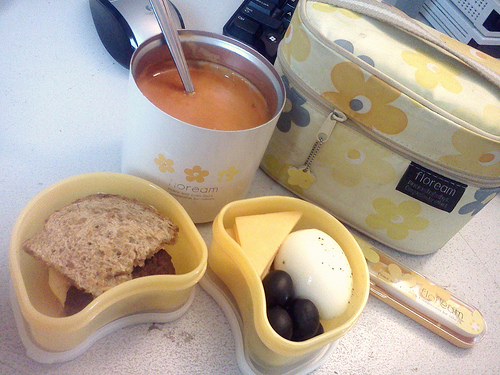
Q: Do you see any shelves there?
A: No, there are no shelves.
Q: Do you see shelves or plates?
A: No, there are no shelves or plates.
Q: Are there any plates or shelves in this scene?
A: No, there are no shelves or plates.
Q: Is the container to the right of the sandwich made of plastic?
A: Yes, the container is made of plastic.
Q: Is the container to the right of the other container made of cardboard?
A: No, the container is made of plastic.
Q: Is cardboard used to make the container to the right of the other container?
A: No, the container is made of plastic.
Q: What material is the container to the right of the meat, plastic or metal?
A: The container is made of plastic.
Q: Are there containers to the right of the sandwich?
A: Yes, there is a container to the right of the sandwich.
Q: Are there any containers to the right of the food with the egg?
A: Yes, there is a container to the right of the sandwich.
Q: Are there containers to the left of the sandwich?
A: No, the container is to the right of the sandwich.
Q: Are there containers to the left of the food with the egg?
A: No, the container is to the right of the sandwich.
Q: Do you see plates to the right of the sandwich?
A: No, there is a container to the right of the sandwich.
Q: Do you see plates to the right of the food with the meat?
A: No, there is a container to the right of the sandwich.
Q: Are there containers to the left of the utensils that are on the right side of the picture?
A: Yes, there is a container to the left of the utensils.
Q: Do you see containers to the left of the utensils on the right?
A: Yes, there is a container to the left of the utensils.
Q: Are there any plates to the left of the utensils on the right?
A: No, there is a container to the left of the utensils.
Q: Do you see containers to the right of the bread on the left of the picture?
A: Yes, there is a container to the right of the bread.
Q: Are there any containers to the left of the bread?
A: No, the container is to the right of the bread.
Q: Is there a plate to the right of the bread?
A: No, there is a container to the right of the bread.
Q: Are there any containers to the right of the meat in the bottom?
A: Yes, there is a container to the right of the meat.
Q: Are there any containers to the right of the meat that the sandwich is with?
A: Yes, there is a container to the right of the meat.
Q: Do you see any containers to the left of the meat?
A: No, the container is to the right of the meat.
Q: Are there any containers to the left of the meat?
A: No, the container is to the right of the meat.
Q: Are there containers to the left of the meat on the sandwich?
A: No, the container is to the right of the meat.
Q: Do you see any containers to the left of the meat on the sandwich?
A: No, the container is to the right of the meat.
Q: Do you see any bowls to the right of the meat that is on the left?
A: No, there is a container to the right of the meat.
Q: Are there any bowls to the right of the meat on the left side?
A: No, there is a container to the right of the meat.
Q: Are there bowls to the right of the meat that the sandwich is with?
A: No, there is a container to the right of the meat.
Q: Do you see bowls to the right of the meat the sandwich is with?
A: No, there is a container to the right of the meat.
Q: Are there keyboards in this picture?
A: Yes, there is a keyboard.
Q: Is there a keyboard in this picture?
A: Yes, there is a keyboard.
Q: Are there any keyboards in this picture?
A: Yes, there is a keyboard.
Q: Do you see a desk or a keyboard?
A: Yes, there is a keyboard.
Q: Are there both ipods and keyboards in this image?
A: No, there is a keyboard but no ipods.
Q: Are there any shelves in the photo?
A: No, there are no shelves.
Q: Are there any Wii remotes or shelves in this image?
A: No, there are no shelves or Wii remotes.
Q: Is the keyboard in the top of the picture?
A: Yes, the keyboard is in the top of the image.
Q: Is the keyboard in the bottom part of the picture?
A: No, the keyboard is in the top of the image.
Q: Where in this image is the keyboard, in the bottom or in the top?
A: The keyboard is in the top of the image.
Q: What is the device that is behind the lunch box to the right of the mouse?
A: The device is a keyboard.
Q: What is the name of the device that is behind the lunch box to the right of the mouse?
A: The device is a keyboard.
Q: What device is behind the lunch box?
A: The device is a keyboard.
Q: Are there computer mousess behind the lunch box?
A: No, there is a keyboard behind the lunch box.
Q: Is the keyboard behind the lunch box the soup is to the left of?
A: Yes, the keyboard is behind the lunch box.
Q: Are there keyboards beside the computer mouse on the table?
A: Yes, there is a keyboard beside the mouse.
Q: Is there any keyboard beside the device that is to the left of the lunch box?
A: Yes, there is a keyboard beside the mouse.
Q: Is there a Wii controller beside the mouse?
A: No, there is a keyboard beside the mouse.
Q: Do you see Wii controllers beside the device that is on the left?
A: No, there is a keyboard beside the mouse.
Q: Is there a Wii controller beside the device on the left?
A: No, there is a keyboard beside the mouse.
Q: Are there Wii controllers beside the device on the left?
A: No, there is a keyboard beside the mouse.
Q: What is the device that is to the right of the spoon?
A: The device is a keyboard.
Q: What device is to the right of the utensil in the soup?
A: The device is a keyboard.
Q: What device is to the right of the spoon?
A: The device is a keyboard.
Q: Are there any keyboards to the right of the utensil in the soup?
A: Yes, there is a keyboard to the right of the spoon.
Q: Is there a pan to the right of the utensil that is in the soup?
A: No, there is a keyboard to the right of the spoon.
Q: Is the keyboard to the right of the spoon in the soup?
A: Yes, the keyboard is to the right of the spoon.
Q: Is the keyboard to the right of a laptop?
A: No, the keyboard is to the right of the spoon.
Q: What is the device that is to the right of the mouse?
A: The device is a keyboard.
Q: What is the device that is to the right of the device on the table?
A: The device is a keyboard.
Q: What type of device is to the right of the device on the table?
A: The device is a keyboard.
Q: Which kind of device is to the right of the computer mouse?
A: The device is a keyboard.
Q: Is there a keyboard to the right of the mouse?
A: Yes, there is a keyboard to the right of the mouse.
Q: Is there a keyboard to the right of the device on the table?
A: Yes, there is a keyboard to the right of the mouse.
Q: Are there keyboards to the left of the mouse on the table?
A: No, the keyboard is to the right of the computer mouse.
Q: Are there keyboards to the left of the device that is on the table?
A: No, the keyboard is to the right of the computer mouse.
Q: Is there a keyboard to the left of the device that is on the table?
A: No, the keyboard is to the right of the computer mouse.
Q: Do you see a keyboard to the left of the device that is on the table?
A: No, the keyboard is to the right of the computer mouse.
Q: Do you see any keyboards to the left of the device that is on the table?
A: No, the keyboard is to the right of the computer mouse.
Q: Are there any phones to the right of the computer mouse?
A: No, there is a keyboard to the right of the computer mouse.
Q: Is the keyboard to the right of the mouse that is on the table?
A: Yes, the keyboard is to the right of the computer mouse.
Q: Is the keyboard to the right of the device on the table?
A: Yes, the keyboard is to the right of the computer mouse.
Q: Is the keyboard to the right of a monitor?
A: No, the keyboard is to the right of the computer mouse.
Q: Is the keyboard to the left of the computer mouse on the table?
A: No, the keyboard is to the right of the computer mouse.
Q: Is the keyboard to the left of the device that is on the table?
A: No, the keyboard is to the right of the computer mouse.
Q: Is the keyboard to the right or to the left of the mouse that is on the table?
A: The keyboard is to the right of the mouse.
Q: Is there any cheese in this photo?
A: Yes, there is cheese.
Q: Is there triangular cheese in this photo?
A: Yes, there is triangular cheese.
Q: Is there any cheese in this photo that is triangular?
A: Yes, there is cheese that is triangular.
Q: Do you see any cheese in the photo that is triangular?
A: Yes, there is cheese that is triangular.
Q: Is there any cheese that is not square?
A: Yes, there is triangular cheese.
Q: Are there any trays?
A: No, there are no trays.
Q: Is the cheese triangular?
A: Yes, the cheese is triangular.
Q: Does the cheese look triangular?
A: Yes, the cheese is triangular.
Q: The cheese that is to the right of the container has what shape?
A: The cheese is triangular.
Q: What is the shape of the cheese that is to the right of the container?
A: The cheese is triangular.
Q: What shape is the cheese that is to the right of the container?
A: The cheese is triangular.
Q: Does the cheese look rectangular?
A: No, the cheese is triangular.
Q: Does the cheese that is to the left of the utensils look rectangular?
A: No, the cheese is triangular.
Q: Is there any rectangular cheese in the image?
A: No, there is cheese but it is triangular.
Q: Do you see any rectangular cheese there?
A: No, there is cheese but it is triangular.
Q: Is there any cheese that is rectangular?
A: No, there is cheese but it is triangular.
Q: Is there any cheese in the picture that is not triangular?
A: No, there is cheese but it is triangular.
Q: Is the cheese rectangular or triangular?
A: The cheese is triangular.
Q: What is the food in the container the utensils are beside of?
A: The food is cheese.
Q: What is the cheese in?
A: The cheese is in the container.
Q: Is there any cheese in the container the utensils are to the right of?
A: Yes, there is cheese in the container.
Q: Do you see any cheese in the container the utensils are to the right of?
A: Yes, there is cheese in the container.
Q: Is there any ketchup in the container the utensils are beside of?
A: No, there is cheese in the container.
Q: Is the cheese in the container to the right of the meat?
A: Yes, the cheese is in the container.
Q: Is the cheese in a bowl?
A: No, the cheese is in the container.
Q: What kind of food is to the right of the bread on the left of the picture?
A: The food is cheese.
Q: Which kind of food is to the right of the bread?
A: The food is cheese.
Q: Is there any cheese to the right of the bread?
A: Yes, there is cheese to the right of the bread.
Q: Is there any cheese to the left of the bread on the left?
A: No, the cheese is to the right of the bread.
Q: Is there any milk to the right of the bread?
A: No, there is cheese to the right of the bread.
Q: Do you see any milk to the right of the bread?
A: No, there is cheese to the right of the bread.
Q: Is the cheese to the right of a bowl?
A: No, the cheese is to the right of the bread.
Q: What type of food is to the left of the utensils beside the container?
A: The food is cheese.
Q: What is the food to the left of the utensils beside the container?
A: The food is cheese.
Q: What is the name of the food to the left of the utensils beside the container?
A: The food is cheese.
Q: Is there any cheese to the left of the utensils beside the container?
A: Yes, there is cheese to the left of the utensils.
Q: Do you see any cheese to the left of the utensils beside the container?
A: Yes, there is cheese to the left of the utensils.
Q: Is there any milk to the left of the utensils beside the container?
A: No, there is cheese to the left of the utensils.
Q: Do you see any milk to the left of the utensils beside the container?
A: No, there is cheese to the left of the utensils.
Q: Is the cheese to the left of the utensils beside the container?
A: Yes, the cheese is to the left of the utensils.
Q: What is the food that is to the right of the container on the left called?
A: The food is cheese.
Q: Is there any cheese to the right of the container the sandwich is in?
A: Yes, there is cheese to the right of the container.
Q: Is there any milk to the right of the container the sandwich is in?
A: No, there is cheese to the right of the container.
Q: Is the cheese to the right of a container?
A: Yes, the cheese is to the right of a container.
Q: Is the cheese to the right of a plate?
A: No, the cheese is to the right of a container.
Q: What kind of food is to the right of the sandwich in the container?
A: The food is cheese.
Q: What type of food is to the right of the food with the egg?
A: The food is cheese.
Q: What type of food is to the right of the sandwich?
A: The food is cheese.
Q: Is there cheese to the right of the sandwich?
A: Yes, there is cheese to the right of the sandwich.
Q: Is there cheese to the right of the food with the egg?
A: Yes, there is cheese to the right of the sandwich.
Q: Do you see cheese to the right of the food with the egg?
A: Yes, there is cheese to the right of the sandwich.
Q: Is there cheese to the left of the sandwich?
A: No, the cheese is to the right of the sandwich.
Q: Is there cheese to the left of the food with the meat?
A: No, the cheese is to the right of the sandwich.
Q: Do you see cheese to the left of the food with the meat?
A: No, the cheese is to the right of the sandwich.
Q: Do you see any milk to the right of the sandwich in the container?
A: No, there is cheese to the right of the sandwich.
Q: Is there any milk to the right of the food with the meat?
A: No, there is cheese to the right of the sandwich.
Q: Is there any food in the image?
A: Yes, there is food.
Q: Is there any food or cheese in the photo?
A: Yes, there is food.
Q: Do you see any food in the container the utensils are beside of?
A: Yes, there is food in the container.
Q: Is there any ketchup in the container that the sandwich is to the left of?
A: No, there is food in the container.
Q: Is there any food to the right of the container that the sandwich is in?
A: Yes, there is food to the right of the container.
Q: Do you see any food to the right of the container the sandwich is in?
A: Yes, there is food to the right of the container.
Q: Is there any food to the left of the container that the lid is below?
A: No, the food is to the right of the container.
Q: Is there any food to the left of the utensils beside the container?
A: Yes, there is food to the left of the utensils.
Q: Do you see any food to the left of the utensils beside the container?
A: Yes, there is food to the left of the utensils.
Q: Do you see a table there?
A: Yes, there is a table.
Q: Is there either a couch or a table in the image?
A: Yes, there is a table.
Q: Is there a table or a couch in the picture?
A: Yes, there is a table.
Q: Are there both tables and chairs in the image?
A: No, there is a table but no chairs.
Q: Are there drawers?
A: No, there are no drawers.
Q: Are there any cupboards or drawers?
A: No, there are no drawers or cupboards.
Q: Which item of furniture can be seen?
A: The piece of furniture is a table.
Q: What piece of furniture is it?
A: The piece of furniture is a table.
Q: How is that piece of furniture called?
A: This is a table.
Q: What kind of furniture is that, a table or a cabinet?
A: This is a table.